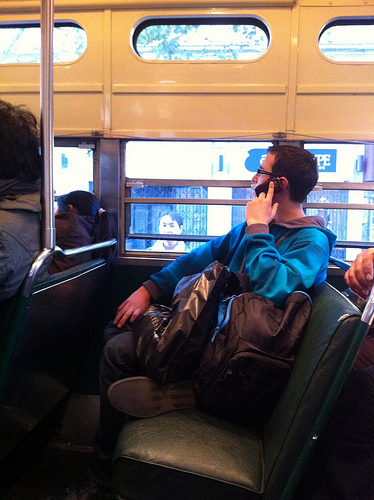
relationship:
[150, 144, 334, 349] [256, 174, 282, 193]
man on cellphone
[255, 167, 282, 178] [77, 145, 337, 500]
glasses on man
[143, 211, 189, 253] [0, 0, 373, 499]
man on bus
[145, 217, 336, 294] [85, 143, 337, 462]
blue sweater on man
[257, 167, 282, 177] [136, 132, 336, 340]
glasses on man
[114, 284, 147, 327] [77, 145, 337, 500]
hand on man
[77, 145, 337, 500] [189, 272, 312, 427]
man wearing backpack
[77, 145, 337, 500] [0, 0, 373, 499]
man on bus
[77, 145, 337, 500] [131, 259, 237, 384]
man holding bag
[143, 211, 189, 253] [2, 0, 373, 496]
man in train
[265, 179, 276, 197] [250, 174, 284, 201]
index finger on phone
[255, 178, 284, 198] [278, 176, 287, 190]
cell phone to ear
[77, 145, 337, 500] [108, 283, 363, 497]
man on seat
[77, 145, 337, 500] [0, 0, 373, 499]
man sitting on bus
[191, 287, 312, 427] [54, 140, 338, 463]
backpack next to man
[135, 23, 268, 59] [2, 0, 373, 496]
window on train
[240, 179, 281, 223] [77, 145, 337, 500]
hand of man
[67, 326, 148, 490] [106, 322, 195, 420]
leg on top of leg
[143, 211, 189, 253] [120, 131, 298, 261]
man visible through window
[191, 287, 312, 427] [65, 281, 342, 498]
backpack sitting on seat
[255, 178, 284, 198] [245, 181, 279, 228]
cell phone in hand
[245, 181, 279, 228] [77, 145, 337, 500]
hand of man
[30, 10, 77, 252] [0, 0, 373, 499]
pole on a bus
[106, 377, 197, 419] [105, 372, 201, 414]
sole of man's foot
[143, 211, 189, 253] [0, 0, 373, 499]
man outside of bus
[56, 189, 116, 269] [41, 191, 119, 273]
head of woman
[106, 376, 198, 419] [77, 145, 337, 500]
shoe of man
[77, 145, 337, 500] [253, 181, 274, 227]
man on cell phone